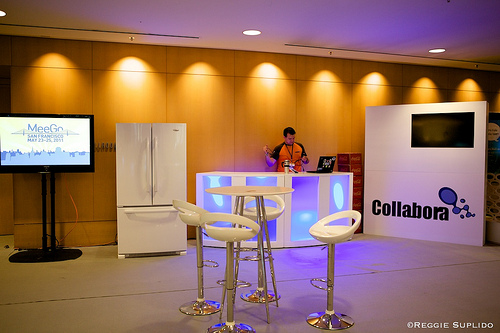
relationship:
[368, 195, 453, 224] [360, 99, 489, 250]
"collabora" on board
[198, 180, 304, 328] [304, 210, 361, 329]
table has stool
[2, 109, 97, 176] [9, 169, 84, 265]
tv on pedestal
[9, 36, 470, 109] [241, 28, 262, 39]
arches are under light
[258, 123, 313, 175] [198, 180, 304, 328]
man behind table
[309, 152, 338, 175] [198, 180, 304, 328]
laptop on table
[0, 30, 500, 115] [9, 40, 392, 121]
arches on wall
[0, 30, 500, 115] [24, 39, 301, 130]
arches on wall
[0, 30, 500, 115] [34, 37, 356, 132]
arches on wall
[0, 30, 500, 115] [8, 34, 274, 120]
arches on wall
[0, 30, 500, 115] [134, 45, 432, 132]
arches on wall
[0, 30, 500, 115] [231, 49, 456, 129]
arches on wall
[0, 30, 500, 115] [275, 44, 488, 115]
arches on wall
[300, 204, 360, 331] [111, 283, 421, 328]
stool on floor